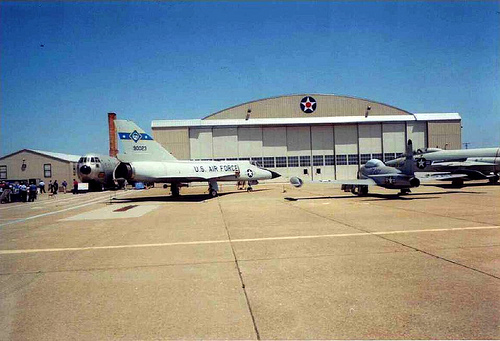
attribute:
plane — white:
[91, 111, 294, 210]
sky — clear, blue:
[194, 0, 433, 174]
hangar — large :
[242, 160, 316, 232]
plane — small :
[52, 114, 253, 228]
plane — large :
[57, 106, 325, 221]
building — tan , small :
[147, 69, 455, 199]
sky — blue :
[33, 19, 439, 160]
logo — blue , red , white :
[264, 75, 341, 125]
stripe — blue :
[89, 86, 144, 155]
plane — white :
[46, 89, 309, 249]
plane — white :
[58, 105, 305, 235]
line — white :
[35, 206, 338, 286]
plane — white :
[40, 100, 311, 238]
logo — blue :
[273, 80, 359, 131]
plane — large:
[93, 107, 283, 197]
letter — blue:
[184, 163, 208, 174]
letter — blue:
[195, 161, 213, 180]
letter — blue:
[206, 161, 219, 176]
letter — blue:
[222, 161, 242, 174]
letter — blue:
[211, 161, 233, 179]